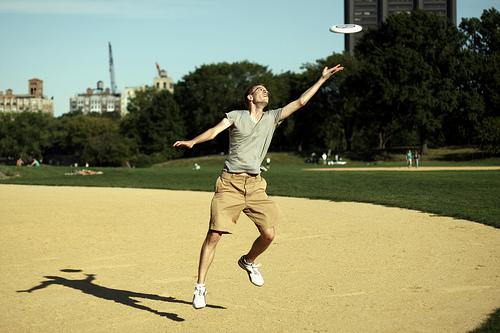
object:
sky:
[0, 0, 499, 120]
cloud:
[0, 0, 499, 118]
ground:
[0, 146, 499, 332]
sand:
[0, 182, 499, 332]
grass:
[0, 150, 499, 233]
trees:
[0, 3, 499, 171]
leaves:
[411, 29, 434, 46]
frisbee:
[327, 22, 364, 34]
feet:
[189, 282, 209, 309]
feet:
[236, 253, 266, 287]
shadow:
[15, 266, 229, 325]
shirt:
[221, 108, 284, 177]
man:
[172, 63, 347, 311]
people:
[26, 158, 40, 168]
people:
[406, 148, 414, 170]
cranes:
[107, 40, 119, 93]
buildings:
[0, 76, 60, 117]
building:
[344, 1, 459, 56]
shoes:
[190, 282, 209, 311]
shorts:
[206, 170, 287, 235]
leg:
[196, 196, 245, 287]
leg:
[243, 199, 276, 263]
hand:
[320, 63, 345, 80]